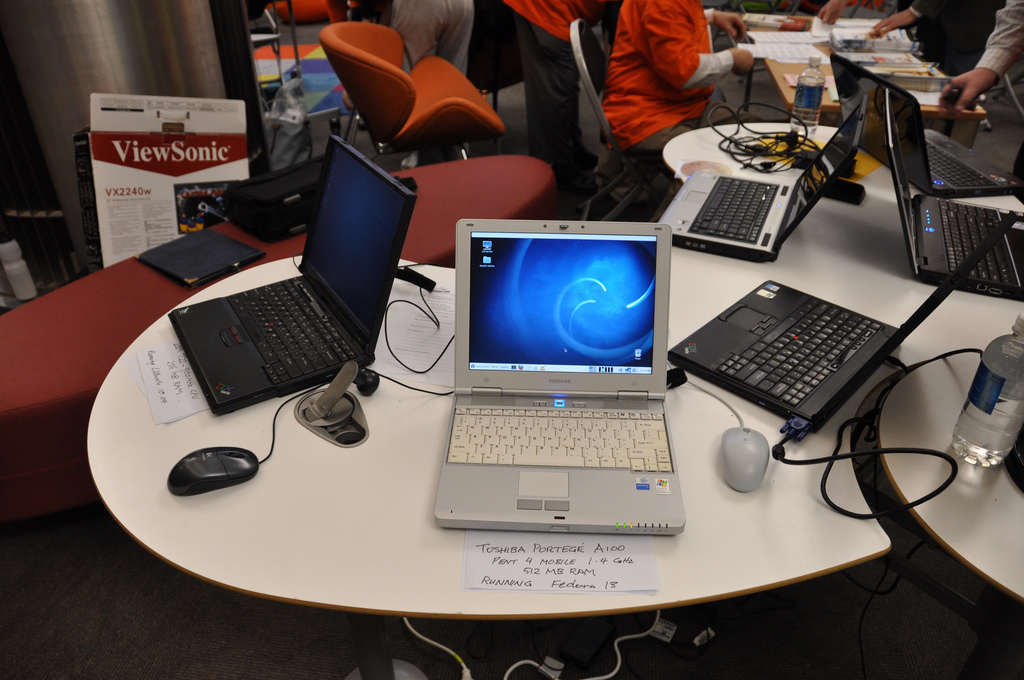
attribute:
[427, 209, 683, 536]
computer — White 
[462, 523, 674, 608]
paper — white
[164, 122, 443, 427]
laptop — black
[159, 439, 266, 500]
mouse — black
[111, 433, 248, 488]
mouse — black